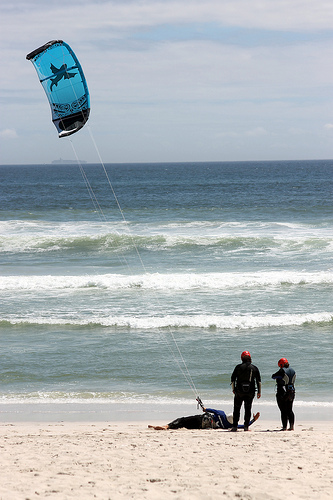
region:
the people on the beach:
[144, 350, 301, 460]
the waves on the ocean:
[1, 214, 329, 338]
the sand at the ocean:
[1, 439, 330, 497]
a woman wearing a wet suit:
[269, 354, 305, 435]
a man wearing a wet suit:
[224, 344, 265, 436]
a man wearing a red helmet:
[237, 348, 253, 363]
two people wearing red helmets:
[234, 345, 295, 373]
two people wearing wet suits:
[233, 346, 297, 438]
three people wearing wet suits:
[143, 347, 303, 435]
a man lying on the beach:
[138, 406, 261, 432]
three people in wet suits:
[137, 339, 299, 436]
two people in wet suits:
[227, 343, 305, 439]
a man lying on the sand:
[142, 405, 261, 436]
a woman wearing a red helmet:
[276, 355, 292, 372]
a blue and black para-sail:
[21, 32, 89, 154]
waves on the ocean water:
[1, 249, 325, 334]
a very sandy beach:
[1, 435, 312, 494]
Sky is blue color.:
[118, 29, 277, 120]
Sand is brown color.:
[28, 434, 173, 484]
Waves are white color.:
[24, 261, 280, 290]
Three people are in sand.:
[142, 337, 319, 440]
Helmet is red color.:
[234, 341, 288, 374]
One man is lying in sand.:
[153, 404, 249, 433]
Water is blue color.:
[133, 171, 269, 201]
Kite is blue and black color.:
[29, 38, 112, 143]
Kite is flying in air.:
[24, 40, 104, 141]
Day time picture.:
[15, 116, 268, 390]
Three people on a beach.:
[131, 345, 300, 452]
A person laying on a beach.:
[148, 402, 259, 437]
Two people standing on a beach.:
[226, 345, 302, 434]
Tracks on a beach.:
[16, 419, 327, 497]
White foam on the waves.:
[7, 220, 328, 338]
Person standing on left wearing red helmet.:
[229, 345, 262, 432]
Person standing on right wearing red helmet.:
[275, 353, 293, 368]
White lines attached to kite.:
[74, 145, 219, 414]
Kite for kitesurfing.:
[21, 32, 100, 139]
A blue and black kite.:
[22, 40, 95, 141]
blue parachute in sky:
[32, 41, 120, 146]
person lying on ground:
[162, 394, 234, 439]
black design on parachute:
[45, 48, 78, 96]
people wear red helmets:
[239, 347, 286, 379]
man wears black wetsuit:
[234, 359, 270, 433]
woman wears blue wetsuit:
[272, 354, 302, 432]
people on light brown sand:
[28, 429, 289, 488]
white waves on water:
[45, 222, 315, 330]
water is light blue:
[39, 199, 306, 355]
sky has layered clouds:
[97, 1, 325, 135]